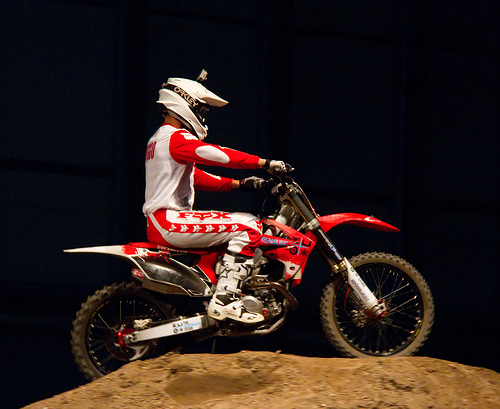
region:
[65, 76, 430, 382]
the man is on a bike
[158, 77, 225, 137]
the man is wearing a white helmet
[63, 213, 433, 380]
the bike is red and white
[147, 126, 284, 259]
the make has a biking suit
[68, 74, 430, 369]
the suit matches the color of the bike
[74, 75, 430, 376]
the bike is on a dirt hill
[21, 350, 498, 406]
the dirt hill is brown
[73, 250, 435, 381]
the bike has two wheels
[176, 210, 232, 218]
the suit has the word fox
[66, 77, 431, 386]
the man sits on the bike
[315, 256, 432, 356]
The front tire of the dirt bike.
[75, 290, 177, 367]
The back tire of the dirt bike.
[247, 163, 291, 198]
The handle bars of the dirt bike.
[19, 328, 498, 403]
The mound of dirt the rider is on.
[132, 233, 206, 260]
The seat of the dirt bike.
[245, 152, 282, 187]
The gloves the rider is wearing.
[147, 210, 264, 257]
The pants the rider is wearing.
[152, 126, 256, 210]
The shirt the rider is wearing.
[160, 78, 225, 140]
The helmet the rider is wearing.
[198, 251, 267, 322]
The boot the rider is wearing.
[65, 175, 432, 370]
red and white motorbike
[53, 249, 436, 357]
black tires of motorbike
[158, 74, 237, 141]
white helmet of rider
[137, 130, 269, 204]
red and white shirt of rider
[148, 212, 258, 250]
red and white pants of rider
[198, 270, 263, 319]
white boot of rider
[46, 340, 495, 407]
mound of dirt bike is sitting on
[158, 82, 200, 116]
black strap of rider's goggles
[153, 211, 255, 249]
red stripe on white pants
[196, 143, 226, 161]
white elbow patch on sleeve of shirt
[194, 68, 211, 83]
CAMERA IS ON TOP OF HELMET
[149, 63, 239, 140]
PERSON IS WEARING A HELMET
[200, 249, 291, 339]
PERSON IS WEARING HEAVY BOOTS FOR SAFETY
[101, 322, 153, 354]
CENTER OF BACK TIRE IS RED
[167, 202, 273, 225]
WORD ON SIDE OF PATS IS FOX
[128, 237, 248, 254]
SEAT OF MOTORCYCLE IS RED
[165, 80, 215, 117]
PERSON IS WEARING GOGGLES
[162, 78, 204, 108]
WORDING ON GOGGLES IS OAKLEY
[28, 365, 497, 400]
DIRT IS BELOW THE MOTORCYCLE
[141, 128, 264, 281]
PERSON IS WEARING A RED AND WHITE OUTFIT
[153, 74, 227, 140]
a white motorcycle helmet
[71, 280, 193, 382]
a motorcycle rear tire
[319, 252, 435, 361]
a motorcycle front tire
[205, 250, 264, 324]
a white and black motorcycle boot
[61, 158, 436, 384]
a red and white motorcycle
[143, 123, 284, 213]
a red and white shirt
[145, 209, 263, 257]
a pair of red and white pants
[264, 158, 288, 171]
a black and white motorcycle glove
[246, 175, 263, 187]
a black and white motorcycle glove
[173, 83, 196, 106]
printed OAKLEY corporate logo